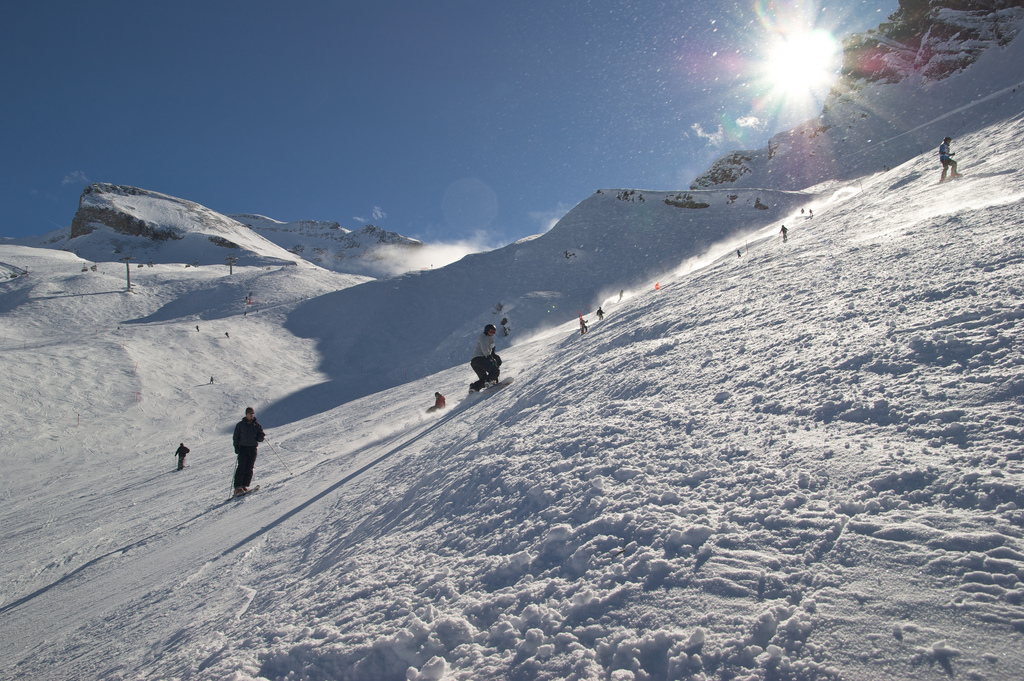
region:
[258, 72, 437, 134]
a view of sky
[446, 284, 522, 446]
man in the snow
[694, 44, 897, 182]
a view of sun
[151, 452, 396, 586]
a view of lines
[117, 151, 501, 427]
a view of mountains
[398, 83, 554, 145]
a view of clouds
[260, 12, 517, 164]
blue and clear sky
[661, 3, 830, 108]
sun is brightly shining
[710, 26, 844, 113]
sun is bright white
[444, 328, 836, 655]
many tracks in snow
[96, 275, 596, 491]
people skiing on snow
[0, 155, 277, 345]
mountain is snow covered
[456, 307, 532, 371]
person has white coat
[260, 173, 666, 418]
long shadow on mountain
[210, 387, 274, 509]
Person on a hill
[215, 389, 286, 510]
Person is on a hill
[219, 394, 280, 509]
Person on a snowy hill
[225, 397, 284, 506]
Person is on a snowy hill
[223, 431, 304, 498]
Person holding ski poles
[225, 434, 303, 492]
Person is holding ski poles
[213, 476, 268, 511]
Person is on skis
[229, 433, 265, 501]
Person is wearing pants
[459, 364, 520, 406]
Person is on a snowboard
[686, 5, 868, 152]
sun is very bright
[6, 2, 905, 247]
sky is very clear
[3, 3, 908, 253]
sky is very blue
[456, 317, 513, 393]
snowboarder on snowy hillside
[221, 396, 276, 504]
man standing on snowboard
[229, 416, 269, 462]
man wearing black coat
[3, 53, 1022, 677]
snow on hill side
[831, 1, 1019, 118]
rocky top part of mountain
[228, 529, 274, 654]
tracks in snow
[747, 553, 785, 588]
snow on the ground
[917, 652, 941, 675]
snow on the ground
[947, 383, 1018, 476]
snow on the ground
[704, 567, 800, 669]
snow on the ground